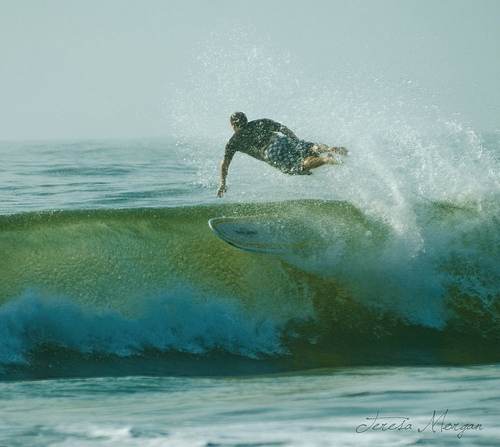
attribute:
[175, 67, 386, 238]
surfer — off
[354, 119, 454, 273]
splash — large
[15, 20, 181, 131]
view — partial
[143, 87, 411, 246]
man — surfing, air, behind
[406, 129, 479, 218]
sea — foam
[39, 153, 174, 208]
area — ocean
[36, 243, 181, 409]
ocean — part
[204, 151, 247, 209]
arm — part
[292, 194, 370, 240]
wave — edge, big, blue, hit, dark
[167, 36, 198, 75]
cloud — part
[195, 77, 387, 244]
guy — hitting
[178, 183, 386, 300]
board — surf, yellow, white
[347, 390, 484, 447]
name — imprinted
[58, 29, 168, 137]
sky — gloomy, cloudy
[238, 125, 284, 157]
shirt — black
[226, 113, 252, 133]
hair — dark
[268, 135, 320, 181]
short — white